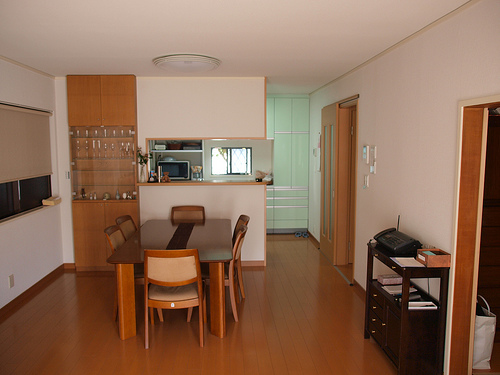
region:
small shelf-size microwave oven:
[151, 163, 191, 185]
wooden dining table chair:
[131, 245, 213, 353]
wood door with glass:
[315, 98, 358, 273]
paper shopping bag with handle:
[467, 290, 497, 371]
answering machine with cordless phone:
[371, 212, 419, 253]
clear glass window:
[265, 95, 313, 240]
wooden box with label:
[411, 241, 453, 274]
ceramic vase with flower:
[137, 146, 152, 186]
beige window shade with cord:
[0, 103, 56, 226]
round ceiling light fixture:
[148, 50, 226, 79]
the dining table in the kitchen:
[101, 205, 254, 341]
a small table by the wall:
[361, 231, 447, 373]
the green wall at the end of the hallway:
[266, 94, 309, 231]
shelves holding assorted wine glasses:
[71, 127, 134, 199]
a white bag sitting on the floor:
[477, 297, 497, 368]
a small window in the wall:
[210, 149, 250, 172]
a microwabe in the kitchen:
[158, 160, 188, 180]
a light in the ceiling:
[149, 52, 220, 76]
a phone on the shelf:
[373, 218, 411, 255]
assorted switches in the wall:
[357, 142, 380, 192]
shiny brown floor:
[247, 331, 354, 348]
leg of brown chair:
[128, 314, 180, 343]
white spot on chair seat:
[161, 294, 191, 320]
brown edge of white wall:
[30, 262, 69, 297]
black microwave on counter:
[153, 154, 200, 180]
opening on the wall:
[208, 142, 271, 185]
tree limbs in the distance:
[212, 151, 242, 171]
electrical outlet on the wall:
[2, 270, 44, 295]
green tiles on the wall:
[279, 109, 306, 196]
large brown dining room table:
[96, 184, 273, 326]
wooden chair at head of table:
[138, 247, 210, 354]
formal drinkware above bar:
[69, 121, 137, 163]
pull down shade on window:
[0, 98, 55, 205]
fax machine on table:
[373, 223, 424, 258]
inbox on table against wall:
[415, 242, 455, 274]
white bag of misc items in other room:
[476, 298, 498, 373]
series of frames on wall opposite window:
[359, 138, 381, 193]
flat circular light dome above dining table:
[148, 51, 223, 76]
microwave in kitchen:
[156, 156, 193, 178]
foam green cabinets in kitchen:
[266, 89, 311, 236]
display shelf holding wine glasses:
[67, 125, 138, 203]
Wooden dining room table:
[110, 211, 242, 341]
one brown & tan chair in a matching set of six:
[141, 250, 204, 346]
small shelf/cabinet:
[365, 220, 448, 373]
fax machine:
[370, 225, 418, 255]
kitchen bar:
[136, 180, 262, 266]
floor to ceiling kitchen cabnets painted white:
[265, 95, 310, 233]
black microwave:
[152, 160, 187, 180]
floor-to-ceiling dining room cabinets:
[65, 72, 135, 272]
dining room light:
[151, 51, 222, 76]